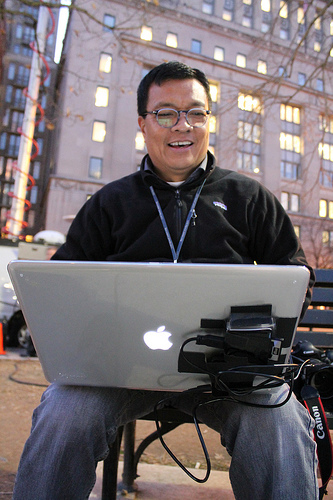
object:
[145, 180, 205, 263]
lanyard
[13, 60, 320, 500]
man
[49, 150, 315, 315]
pullover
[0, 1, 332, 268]
background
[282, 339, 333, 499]
camera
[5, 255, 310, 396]
laptop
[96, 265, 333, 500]
bench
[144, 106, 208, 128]
glasses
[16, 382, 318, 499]
jeans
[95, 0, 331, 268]
tree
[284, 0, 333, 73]
branches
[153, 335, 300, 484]
wires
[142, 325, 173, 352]
logo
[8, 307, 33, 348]
car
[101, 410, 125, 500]
legs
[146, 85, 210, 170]
face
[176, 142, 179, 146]
teeth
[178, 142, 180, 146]
gap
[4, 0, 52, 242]
antenna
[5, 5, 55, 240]
cord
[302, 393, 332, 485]
strap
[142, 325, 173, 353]
apple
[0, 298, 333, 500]
park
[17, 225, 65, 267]
tv van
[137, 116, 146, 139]
ear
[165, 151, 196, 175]
chin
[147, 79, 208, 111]
forehead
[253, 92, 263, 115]
window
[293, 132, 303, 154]
window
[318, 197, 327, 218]
window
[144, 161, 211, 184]
neck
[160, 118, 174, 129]
reflection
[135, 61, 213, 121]
hair